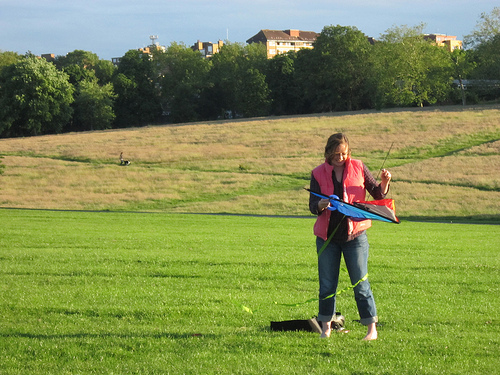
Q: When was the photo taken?
A: Afernoon.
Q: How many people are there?
A: One.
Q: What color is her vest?
A: Red.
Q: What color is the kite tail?
A: Green.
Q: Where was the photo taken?
A: Field.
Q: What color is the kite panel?
A: Blue.